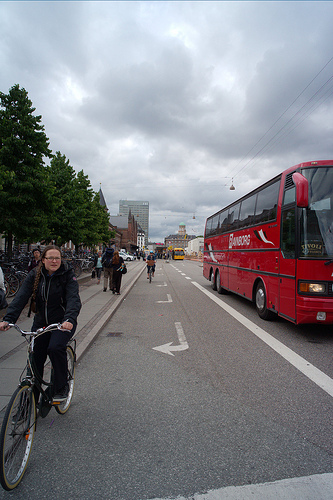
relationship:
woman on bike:
[15, 248, 105, 333] [2, 357, 83, 476]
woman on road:
[15, 248, 105, 333] [111, 273, 293, 459]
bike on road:
[2, 357, 83, 476] [111, 273, 293, 459]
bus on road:
[214, 160, 326, 330] [111, 273, 293, 459]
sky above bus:
[91, 12, 296, 134] [214, 160, 326, 330]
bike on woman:
[2, 357, 83, 476] [15, 248, 105, 333]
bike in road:
[2, 357, 83, 476] [111, 273, 293, 459]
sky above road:
[91, 12, 296, 134] [111, 273, 293, 459]